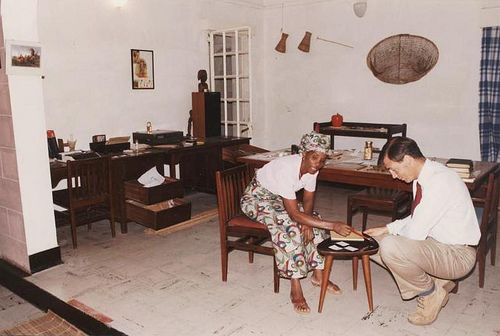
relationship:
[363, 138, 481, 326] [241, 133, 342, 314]
man with woman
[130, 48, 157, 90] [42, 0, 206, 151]
image on wall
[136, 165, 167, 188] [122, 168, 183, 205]
paper in drawer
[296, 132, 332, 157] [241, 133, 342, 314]
wrap on woman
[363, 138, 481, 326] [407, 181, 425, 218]
man has tie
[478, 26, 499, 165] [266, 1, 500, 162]
curtain on wall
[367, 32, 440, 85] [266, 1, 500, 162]
basket on wall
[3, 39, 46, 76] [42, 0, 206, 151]
picture on wall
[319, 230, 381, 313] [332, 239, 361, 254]
stool with papers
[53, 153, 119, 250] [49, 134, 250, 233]
chair under desk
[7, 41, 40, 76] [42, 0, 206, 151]
photo on wall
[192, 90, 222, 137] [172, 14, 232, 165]
speaker in corner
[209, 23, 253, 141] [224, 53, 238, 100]
door has windows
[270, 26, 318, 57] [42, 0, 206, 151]
objects on wall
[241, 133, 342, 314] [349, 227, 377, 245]
woman has pencil